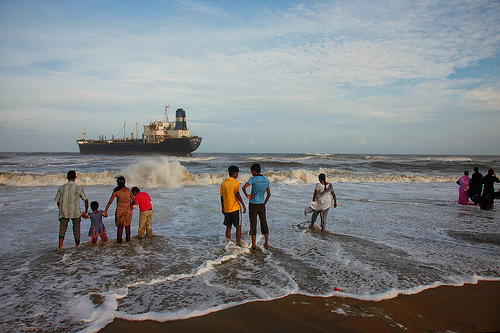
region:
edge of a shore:
[272, 258, 317, 320]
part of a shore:
[373, 280, 418, 325]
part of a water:
[163, 219, 208, 286]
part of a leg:
[258, 224, 273, 265]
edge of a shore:
[356, 265, 386, 300]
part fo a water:
[171, 192, 195, 234]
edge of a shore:
[298, 280, 336, 322]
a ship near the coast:
[78, 104, 202, 155]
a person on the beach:
[52, 170, 89, 250]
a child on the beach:
[81, 200, 110, 247]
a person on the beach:
[102, 175, 137, 243]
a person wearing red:
[128, 184, 155, 239]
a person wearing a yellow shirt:
[219, 162, 248, 248]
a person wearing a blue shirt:
[241, 160, 273, 250]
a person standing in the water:
[302, 170, 340, 235]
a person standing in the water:
[456, 167, 473, 204]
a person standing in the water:
[479, 165, 498, 210]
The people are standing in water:
[453, 165, 499, 215]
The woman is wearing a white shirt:
[307, 172, 340, 237]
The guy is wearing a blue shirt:
[241, 160, 274, 250]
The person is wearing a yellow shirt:
[218, 165, 246, 249]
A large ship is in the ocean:
[76, 101, 205, 158]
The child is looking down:
[130, 181, 155, 240]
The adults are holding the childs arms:
[55, 168, 133, 245]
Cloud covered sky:
[3, 2, 499, 144]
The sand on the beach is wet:
[106, 275, 498, 332]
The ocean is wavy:
[3, 153, 499, 330]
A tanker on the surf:
[69, 97, 206, 158]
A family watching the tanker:
[52, 169, 158, 254]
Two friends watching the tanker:
[217, 161, 279, 248]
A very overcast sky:
[0, 2, 495, 154]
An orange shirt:
[219, 174, 243, 216]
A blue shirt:
[246, 175, 270, 206]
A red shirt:
[130, 193, 155, 215]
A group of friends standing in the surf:
[446, 162, 498, 225]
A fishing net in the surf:
[286, 208, 321, 239]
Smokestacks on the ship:
[172, 105, 191, 128]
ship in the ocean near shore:
[69, 106, 208, 153]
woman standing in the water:
[309, 170, 339, 235]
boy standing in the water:
[247, 162, 275, 246]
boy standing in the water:
[216, 156, 246, 240]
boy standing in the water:
[132, 185, 158, 242]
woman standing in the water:
[109, 173, 134, 246]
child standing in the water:
[85, 193, 110, 253]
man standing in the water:
[47, 168, 86, 265]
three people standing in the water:
[447, 150, 499, 220]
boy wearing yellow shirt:
[220, 169, 238, 240]